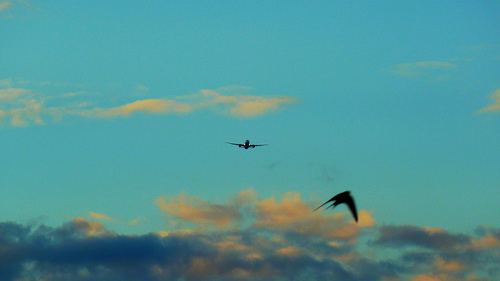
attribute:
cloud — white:
[1, 72, 301, 129]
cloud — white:
[154, 180, 378, 247]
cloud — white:
[2, 213, 497, 278]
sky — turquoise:
[173, 25, 296, 68]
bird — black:
[298, 179, 370, 239]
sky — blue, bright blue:
[2, 1, 499, 279]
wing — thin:
[218, 140, 244, 150]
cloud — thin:
[5, 80, 298, 123]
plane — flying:
[219, 126, 319, 168]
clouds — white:
[6, 81, 292, 127]